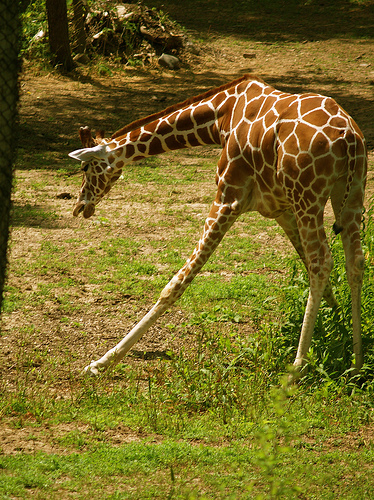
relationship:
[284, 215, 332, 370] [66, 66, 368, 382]
leg on big giraffe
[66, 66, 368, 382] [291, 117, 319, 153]
big giraffe has spots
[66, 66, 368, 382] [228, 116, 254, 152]
big giraffe has spots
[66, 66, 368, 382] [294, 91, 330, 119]
big giraffe has spots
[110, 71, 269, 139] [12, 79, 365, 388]
mane on giraffe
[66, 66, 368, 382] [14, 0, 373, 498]
big giraffe on field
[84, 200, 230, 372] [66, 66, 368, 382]
front leg on big giraffe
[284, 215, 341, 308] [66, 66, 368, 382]
leg on big giraffe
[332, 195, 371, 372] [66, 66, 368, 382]
leg on big giraffe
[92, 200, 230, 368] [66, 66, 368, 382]
front leg on big giraffe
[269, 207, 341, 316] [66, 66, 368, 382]
front leg on big giraffe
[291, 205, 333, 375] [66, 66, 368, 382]
back leg on big giraffe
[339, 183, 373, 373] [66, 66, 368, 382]
back leg on big giraffe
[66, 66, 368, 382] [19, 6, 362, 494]
big giraffe at park